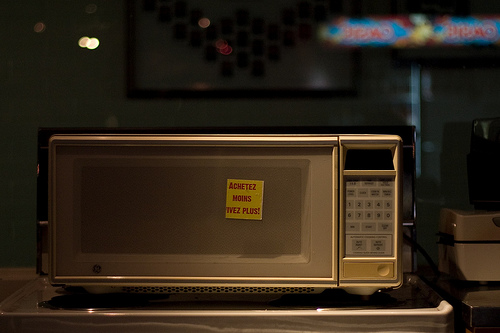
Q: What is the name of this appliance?
A: Microwave.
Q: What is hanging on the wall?
A: A picture frame.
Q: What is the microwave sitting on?
A: A countertop.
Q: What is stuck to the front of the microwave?
A: A yellow sticker.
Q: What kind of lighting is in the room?
A: Dark.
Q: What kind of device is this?
A: A microwave.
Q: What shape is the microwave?
A: Rectangular.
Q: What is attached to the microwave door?
A: A piece of paper.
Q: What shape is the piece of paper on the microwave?
A: Square.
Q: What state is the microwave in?
A: It is turned off.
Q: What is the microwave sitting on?
A: A counter.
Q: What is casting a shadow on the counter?
A: The microwave.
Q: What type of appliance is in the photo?
A: Microwave.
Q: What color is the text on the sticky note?
A: Red.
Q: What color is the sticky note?
A: Yellow.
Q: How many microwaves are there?
A: One.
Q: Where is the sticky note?
A: On the microwave.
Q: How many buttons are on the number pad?
A: 22.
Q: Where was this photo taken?
A: Kitchen.